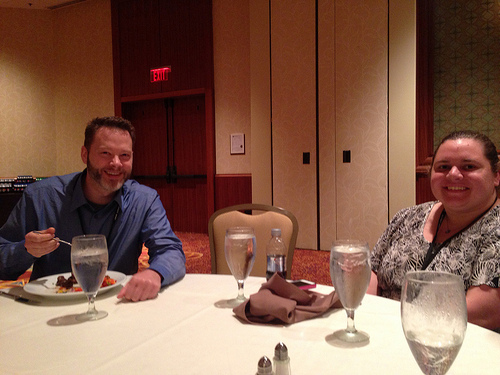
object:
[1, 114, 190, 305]
man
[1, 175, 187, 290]
shirt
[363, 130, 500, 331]
woman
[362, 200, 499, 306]
shirt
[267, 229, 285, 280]
bottle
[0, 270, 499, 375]
table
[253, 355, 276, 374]
shaker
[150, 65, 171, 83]
sign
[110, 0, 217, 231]
door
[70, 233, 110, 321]
glass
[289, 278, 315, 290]
phone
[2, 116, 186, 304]
people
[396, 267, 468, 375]
glasses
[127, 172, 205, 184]
bar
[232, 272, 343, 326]
cloth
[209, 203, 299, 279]
chair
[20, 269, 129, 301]
plate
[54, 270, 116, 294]
food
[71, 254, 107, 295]
water